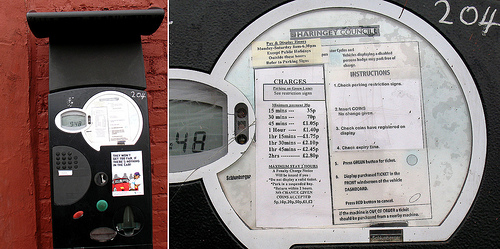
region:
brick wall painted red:
[2, 3, 165, 244]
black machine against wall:
[29, 7, 161, 247]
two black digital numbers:
[174, 130, 212, 154]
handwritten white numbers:
[434, 0, 498, 32]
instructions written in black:
[332, 66, 429, 219]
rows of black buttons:
[51, 148, 79, 173]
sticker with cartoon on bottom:
[111, 151, 142, 197]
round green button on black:
[95, 197, 108, 212]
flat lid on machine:
[24, 4, 165, 43]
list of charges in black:
[266, 75, 322, 162]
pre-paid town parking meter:
[49, 31, 149, 244]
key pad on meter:
[52, 145, 81, 175]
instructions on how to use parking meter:
[328, 65, 419, 223]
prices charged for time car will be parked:
[261, 74, 323, 163]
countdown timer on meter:
[63, 114, 85, 130]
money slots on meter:
[83, 204, 148, 244]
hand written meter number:
[433, 2, 499, 32]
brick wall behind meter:
[26, 35, 167, 247]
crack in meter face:
[172, 108, 257, 207]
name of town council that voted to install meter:
[288, 25, 381, 37]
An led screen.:
[167, 75, 240, 191]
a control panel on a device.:
[52, 138, 95, 180]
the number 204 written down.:
[433, 3, 498, 51]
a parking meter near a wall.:
[37, 8, 164, 247]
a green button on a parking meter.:
[94, 190, 111, 212]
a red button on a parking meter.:
[69, 203, 86, 225]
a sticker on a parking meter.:
[77, 80, 157, 162]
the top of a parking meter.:
[13, 6, 183, 54]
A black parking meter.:
[27, 3, 165, 248]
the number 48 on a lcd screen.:
[172, 123, 220, 167]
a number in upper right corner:
[429, 0, 497, 37]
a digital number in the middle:
[165, 121, 214, 161]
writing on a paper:
[246, 21, 432, 231]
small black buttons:
[51, 147, 92, 184]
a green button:
[93, 196, 111, 217]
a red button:
[64, 208, 85, 220]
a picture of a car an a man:
[110, 148, 145, 193]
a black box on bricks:
[48, 36, 154, 247]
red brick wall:
[18, 45, 45, 201]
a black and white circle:
[406, 153, 418, 168]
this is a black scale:
[166, 33, 379, 218]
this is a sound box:
[33, 40, 128, 245]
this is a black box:
[67, 79, 109, 214]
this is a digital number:
[185, 111, 250, 226]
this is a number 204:
[431, 7, 498, 58]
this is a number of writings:
[217, 89, 383, 221]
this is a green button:
[99, 191, 115, 203]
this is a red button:
[67, 196, 103, 232]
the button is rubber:
[27, 188, 114, 213]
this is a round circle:
[73, 84, 135, 144]